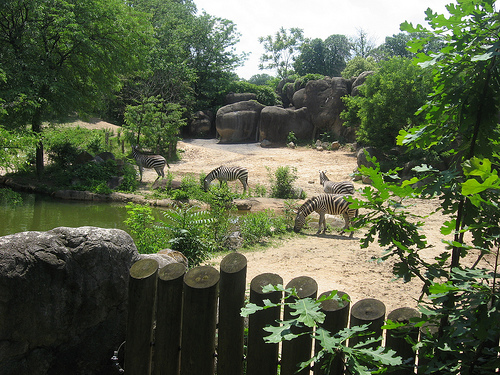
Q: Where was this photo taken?
A: At a zoo.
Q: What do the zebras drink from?
A: The pond.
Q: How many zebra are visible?
A: 4.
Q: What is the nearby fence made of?
A: Wood posts.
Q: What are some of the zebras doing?
A: Grazing.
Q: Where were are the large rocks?
A: At the back of the enclosure.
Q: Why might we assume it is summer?
A: The trees are in full bloom.